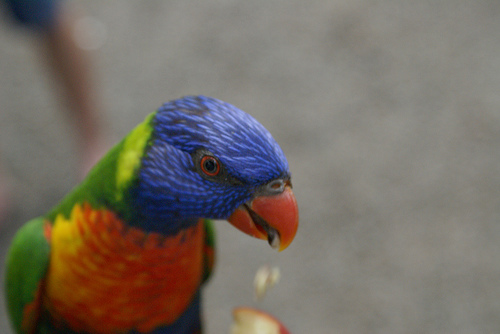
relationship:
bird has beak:
[3, 90, 297, 327] [223, 186, 314, 261]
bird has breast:
[3, 90, 297, 327] [76, 233, 184, 298]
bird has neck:
[3, 90, 297, 327] [82, 127, 154, 219]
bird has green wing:
[3, 90, 297, 327] [1, 216, 52, 334]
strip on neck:
[115, 111, 153, 204] [90, 114, 205, 233]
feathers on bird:
[52, 221, 195, 313] [3, 90, 297, 327]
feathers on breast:
[52, 263, 151, 313] [76, 233, 184, 298]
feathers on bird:
[52, 263, 151, 313] [3, 90, 297, 327]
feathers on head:
[139, 93, 291, 223] [148, 97, 337, 261]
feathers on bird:
[139, 93, 291, 223] [3, 90, 297, 327]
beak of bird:
[224, 181, 309, 247] [115, 93, 281, 297]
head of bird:
[142, 91, 299, 252] [3, 90, 297, 327]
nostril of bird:
[261, 177, 293, 194] [95, 116, 212, 280]